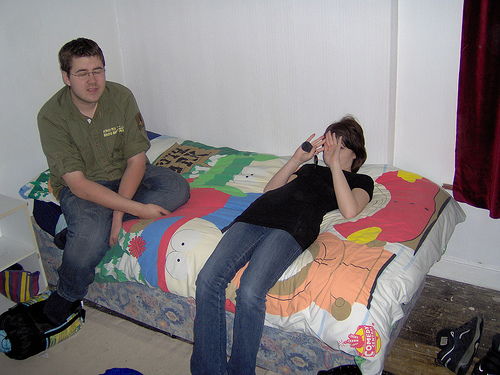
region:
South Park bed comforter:
[91, 137, 468, 374]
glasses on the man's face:
[66, 65, 107, 79]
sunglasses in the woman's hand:
[300, 138, 320, 173]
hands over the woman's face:
[291, 129, 345, 169]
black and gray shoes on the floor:
[431, 312, 499, 372]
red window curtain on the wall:
[450, 0, 499, 219]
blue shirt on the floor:
[93, 363, 146, 373]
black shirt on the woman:
[230, 161, 375, 250]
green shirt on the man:
[36, 79, 153, 200]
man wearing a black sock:
[52, 225, 67, 251]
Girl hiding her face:
[192, 114, 374, 371]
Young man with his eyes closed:
[39, 37, 189, 315]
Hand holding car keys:
[293, 132, 324, 169]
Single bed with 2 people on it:
[29, 129, 460, 374]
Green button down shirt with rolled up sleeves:
[38, 84, 150, 195]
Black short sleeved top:
[235, 161, 374, 251]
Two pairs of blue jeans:
[56, 168, 305, 374]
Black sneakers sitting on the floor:
[433, 314, 498, 373]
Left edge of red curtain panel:
[454, 0, 499, 216]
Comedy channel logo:
[344, 324, 381, 357]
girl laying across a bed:
[191, 115, 375, 374]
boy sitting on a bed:
[36, 36, 189, 324]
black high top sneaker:
[433, 316, 485, 371]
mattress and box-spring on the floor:
[28, 130, 465, 373]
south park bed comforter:
[93, 133, 467, 372]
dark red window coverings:
[452, 1, 499, 218]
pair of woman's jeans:
[190, 220, 302, 373]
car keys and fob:
[301, 139, 318, 167]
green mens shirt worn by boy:
[37, 80, 149, 195]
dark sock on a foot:
[42, 289, 71, 326]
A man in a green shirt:
[30, 33, 182, 181]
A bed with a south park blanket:
[150, 134, 282, 204]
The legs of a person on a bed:
[174, 209, 328, 364]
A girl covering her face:
[269, 100, 414, 219]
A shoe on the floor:
[425, 312, 489, 368]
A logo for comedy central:
[341, 319, 393, 359]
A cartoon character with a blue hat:
[126, 212, 227, 297]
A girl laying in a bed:
[193, 104, 412, 371]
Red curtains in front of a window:
[448, 14, 497, 232]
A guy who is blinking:
[28, 35, 149, 106]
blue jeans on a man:
[54, 164, 187, 301]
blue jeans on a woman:
[188, 222, 304, 373]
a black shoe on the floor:
[433, 309, 488, 372]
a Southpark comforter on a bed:
[54, 130, 467, 373]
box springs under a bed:
[39, 252, 429, 373]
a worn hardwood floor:
[385, 274, 498, 373]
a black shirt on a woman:
[219, 163, 374, 247]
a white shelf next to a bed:
[0, 193, 54, 312]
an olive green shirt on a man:
[37, 79, 147, 196]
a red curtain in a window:
[453, 2, 499, 218]